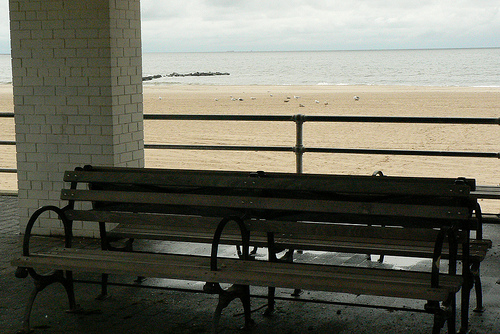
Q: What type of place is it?
A: It is a beach.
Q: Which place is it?
A: It is a beach.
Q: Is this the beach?
A: Yes, it is the beach.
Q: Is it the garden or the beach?
A: It is the beach.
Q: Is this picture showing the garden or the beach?
A: It is showing the beach.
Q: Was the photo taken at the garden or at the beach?
A: It was taken at the beach.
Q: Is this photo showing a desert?
A: No, the picture is showing a beach.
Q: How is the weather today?
A: It is cloudy.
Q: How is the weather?
A: It is cloudy.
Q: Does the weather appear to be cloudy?
A: Yes, it is cloudy.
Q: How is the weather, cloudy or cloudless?
A: It is cloudy.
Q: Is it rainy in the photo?
A: No, it is cloudy.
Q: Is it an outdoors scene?
A: Yes, it is outdoors.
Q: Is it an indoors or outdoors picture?
A: It is outdoors.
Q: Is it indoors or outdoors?
A: It is outdoors.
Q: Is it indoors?
A: No, it is outdoors.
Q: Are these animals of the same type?
A: No, there are both seagulls and birds.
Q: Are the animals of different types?
A: Yes, they are seagulls and birds.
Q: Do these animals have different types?
A: Yes, they are seagulls and birds.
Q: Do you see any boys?
A: No, there are no boys.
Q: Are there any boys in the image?
A: No, there are no boys.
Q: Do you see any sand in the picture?
A: Yes, there is sand.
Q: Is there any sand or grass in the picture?
A: Yes, there is sand.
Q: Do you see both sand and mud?
A: No, there is sand but no mud.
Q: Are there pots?
A: No, there are no pots.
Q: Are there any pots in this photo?
A: No, there are no pots.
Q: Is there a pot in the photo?
A: No, there are no pots.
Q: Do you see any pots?
A: No, there are no pots.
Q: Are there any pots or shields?
A: No, there are no pots or shields.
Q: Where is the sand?
A: The sand is on the beach.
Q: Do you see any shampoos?
A: No, there are no shampoos.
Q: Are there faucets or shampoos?
A: No, there are no shampoos or faucets.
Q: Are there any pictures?
A: No, there are no pictures.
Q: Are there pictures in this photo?
A: No, there are no pictures.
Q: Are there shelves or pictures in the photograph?
A: No, there are no pictures or shelves.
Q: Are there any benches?
A: Yes, there is a bench.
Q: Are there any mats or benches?
A: Yes, there is a bench.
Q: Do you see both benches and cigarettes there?
A: No, there is a bench but no cigarettes.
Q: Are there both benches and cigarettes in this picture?
A: No, there is a bench but no cigarettes.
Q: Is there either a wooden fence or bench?
A: Yes, there is a wood bench.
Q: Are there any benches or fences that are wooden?
A: Yes, the bench is wooden.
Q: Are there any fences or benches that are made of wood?
A: Yes, the bench is made of wood.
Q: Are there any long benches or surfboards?
A: Yes, there is a long bench.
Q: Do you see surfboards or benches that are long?
A: Yes, the bench is long.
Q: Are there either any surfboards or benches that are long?
A: Yes, the bench is long.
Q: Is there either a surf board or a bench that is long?
A: Yes, the bench is long.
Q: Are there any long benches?
A: Yes, there is a long bench.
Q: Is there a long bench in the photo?
A: Yes, there is a long bench.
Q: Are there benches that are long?
A: Yes, there is a bench that is long.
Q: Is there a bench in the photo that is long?
A: Yes, there is a bench that is long.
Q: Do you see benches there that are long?
A: Yes, there is a bench that is long.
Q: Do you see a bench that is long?
A: Yes, there is a bench that is long.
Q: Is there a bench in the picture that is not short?
A: Yes, there is a long bench.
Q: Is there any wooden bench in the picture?
A: Yes, there is a wood bench.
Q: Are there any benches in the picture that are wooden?
A: Yes, there is a bench that is wooden.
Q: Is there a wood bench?
A: Yes, there is a bench that is made of wood.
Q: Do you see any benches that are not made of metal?
A: Yes, there is a bench that is made of wood.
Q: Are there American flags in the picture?
A: No, there are no American flags.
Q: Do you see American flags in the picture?
A: No, there are no American flags.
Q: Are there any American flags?
A: No, there are no American flags.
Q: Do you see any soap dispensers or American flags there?
A: No, there are no American flags or soap dispensers.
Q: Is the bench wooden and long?
A: Yes, the bench is wooden and long.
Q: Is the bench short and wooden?
A: No, the bench is wooden but long.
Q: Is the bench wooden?
A: Yes, the bench is wooden.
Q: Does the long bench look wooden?
A: Yes, the bench is wooden.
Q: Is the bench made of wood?
A: Yes, the bench is made of wood.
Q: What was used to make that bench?
A: The bench is made of wood.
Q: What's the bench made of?
A: The bench is made of wood.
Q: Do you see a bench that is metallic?
A: No, there is a bench but it is wooden.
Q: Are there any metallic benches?
A: No, there is a bench but it is wooden.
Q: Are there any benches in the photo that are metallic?
A: No, there is a bench but it is wooden.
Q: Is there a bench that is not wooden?
A: No, there is a bench but it is wooden.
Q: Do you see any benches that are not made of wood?
A: No, there is a bench but it is made of wood.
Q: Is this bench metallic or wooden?
A: The bench is wooden.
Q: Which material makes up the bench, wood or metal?
A: The bench is made of wood.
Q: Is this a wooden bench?
A: Yes, this is a wooden bench.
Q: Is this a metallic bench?
A: No, this is a wooden bench.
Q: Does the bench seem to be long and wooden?
A: Yes, the bench is long and wooden.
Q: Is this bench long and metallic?
A: No, the bench is long but wooden.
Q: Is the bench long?
A: Yes, the bench is long.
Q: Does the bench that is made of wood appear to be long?
A: Yes, the bench is long.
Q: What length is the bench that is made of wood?
A: The bench is long.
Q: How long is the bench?
A: The bench is long.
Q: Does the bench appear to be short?
A: No, the bench is long.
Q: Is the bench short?
A: No, the bench is long.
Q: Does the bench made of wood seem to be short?
A: No, the bench is long.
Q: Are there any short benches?
A: No, there is a bench but it is long.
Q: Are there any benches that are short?
A: No, there is a bench but it is long.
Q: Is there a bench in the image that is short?
A: No, there is a bench but it is long.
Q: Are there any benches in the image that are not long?
A: No, there is a bench but it is long.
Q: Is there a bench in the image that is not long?
A: No, there is a bench but it is long.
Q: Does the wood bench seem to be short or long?
A: The bench is long.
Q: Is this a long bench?
A: Yes, this is a long bench.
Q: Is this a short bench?
A: No, this is a long bench.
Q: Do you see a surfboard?
A: No, there are no surfboards.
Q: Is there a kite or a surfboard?
A: No, there are no surfboards or kites.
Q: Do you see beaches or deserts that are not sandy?
A: No, there is a beach but it is sandy.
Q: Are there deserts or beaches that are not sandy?
A: No, there is a beach but it is sandy.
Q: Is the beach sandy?
A: Yes, the beach is sandy.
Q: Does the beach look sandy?
A: Yes, the beach is sandy.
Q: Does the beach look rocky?
A: No, the beach is sandy.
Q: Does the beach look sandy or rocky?
A: The beach is sandy.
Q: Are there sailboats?
A: No, there are no sailboats.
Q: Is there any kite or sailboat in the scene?
A: No, there are no sailboats or kites.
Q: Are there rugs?
A: No, there are no rugs.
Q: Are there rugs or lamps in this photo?
A: No, there are no rugs or lamps.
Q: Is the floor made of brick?
A: Yes, the floor is made of brick.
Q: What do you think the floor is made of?
A: The floor is made of brick.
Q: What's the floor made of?
A: The floor is made of brick.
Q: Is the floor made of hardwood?
A: No, the floor is made of brick.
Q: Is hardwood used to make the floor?
A: No, the floor is made of brick.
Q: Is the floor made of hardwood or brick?
A: The floor is made of brick.